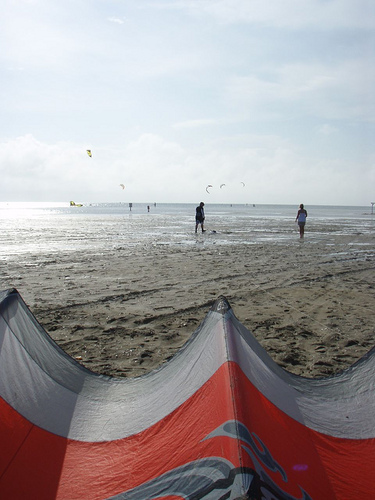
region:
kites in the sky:
[59, 145, 267, 204]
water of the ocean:
[17, 216, 166, 266]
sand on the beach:
[44, 249, 349, 342]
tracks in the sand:
[150, 225, 373, 298]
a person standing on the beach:
[293, 202, 308, 232]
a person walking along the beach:
[193, 201, 207, 232]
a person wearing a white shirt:
[294, 204, 310, 235]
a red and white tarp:
[1, 290, 372, 497]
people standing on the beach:
[181, 196, 317, 238]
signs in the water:
[122, 197, 172, 214]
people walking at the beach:
[187, 187, 334, 251]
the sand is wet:
[50, 223, 125, 255]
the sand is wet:
[55, 202, 115, 247]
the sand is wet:
[65, 214, 136, 244]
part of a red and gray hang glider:
[0, 277, 373, 492]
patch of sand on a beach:
[60, 260, 185, 337]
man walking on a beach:
[189, 199, 210, 236]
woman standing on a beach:
[290, 202, 309, 244]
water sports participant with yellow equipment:
[66, 144, 94, 208]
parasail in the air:
[117, 180, 127, 193]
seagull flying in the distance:
[236, 177, 248, 190]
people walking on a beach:
[47, 194, 373, 254]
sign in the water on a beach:
[125, 200, 134, 212]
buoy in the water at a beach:
[369, 198, 373, 216]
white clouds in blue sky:
[18, 0, 58, 48]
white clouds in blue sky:
[113, 126, 156, 156]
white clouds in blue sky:
[231, 84, 303, 134]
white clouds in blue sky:
[161, 171, 193, 201]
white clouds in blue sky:
[204, 80, 280, 153]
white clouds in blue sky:
[114, 46, 168, 100]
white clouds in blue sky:
[96, 60, 153, 100]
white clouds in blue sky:
[35, 41, 68, 90]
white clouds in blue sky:
[57, 15, 117, 63]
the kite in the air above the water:
[73, 136, 256, 193]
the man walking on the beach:
[189, 198, 210, 238]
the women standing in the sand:
[289, 193, 309, 241]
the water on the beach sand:
[7, 216, 176, 250]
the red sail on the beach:
[0, 283, 373, 498]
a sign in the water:
[125, 199, 138, 211]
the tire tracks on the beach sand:
[61, 276, 183, 345]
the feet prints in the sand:
[282, 297, 353, 322]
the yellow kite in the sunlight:
[82, 146, 97, 162]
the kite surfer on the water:
[66, 197, 96, 209]